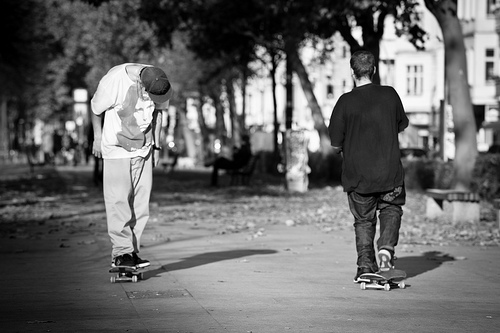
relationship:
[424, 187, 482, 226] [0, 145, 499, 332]
bench in park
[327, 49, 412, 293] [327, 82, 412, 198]
skateboarder wears shirt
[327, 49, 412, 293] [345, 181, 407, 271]
skateboarder wears jeans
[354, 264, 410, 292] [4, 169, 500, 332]
skateboard on pavement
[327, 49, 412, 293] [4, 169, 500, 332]
skateboarder on pavement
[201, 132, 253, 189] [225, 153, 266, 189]
man on bench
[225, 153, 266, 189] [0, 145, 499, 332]
bench in park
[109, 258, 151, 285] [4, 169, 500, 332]
skateboard on pavement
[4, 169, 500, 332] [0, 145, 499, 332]
pavement in park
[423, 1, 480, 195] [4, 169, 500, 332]
tree trunk next to pavement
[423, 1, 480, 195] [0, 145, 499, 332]
tree trunk in park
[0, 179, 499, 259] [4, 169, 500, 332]
leaves are over pavement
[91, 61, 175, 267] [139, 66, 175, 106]
man has head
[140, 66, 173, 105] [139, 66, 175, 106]
baseball hat on head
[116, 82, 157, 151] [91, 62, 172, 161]
jim morrison on tshirt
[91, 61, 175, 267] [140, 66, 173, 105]
man wearing baseball hat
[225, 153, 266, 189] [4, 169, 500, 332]
bench next to pavement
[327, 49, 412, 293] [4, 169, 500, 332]
skateboarder rolling along pavement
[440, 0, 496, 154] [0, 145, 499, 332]
building next to park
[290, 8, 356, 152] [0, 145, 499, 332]
building next to park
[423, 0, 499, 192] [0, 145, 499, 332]
tree next to park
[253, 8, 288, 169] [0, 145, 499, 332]
tree next to park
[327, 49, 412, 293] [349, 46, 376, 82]
skateboarder has hair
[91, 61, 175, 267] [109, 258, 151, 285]
man on skateboard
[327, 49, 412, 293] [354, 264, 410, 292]
skateboarder on skateboard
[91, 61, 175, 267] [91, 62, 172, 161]
man wears tshirt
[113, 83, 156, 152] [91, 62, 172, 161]
face on tshirt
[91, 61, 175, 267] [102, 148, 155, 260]
man wears pants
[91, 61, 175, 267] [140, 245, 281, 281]
man casts shadow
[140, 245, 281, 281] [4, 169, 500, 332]
shadow on pavement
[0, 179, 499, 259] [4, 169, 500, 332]
leaves are on pavement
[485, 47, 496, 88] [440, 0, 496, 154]
window in building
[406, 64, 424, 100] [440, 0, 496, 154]
window in building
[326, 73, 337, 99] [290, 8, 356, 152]
window in building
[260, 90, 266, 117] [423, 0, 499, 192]
window in tree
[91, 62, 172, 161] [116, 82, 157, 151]
tshirt shows jim morrison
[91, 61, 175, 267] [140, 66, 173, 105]
man wears baseball hat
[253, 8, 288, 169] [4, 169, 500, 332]
tree next to pavement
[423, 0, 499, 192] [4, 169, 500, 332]
tree next to pavement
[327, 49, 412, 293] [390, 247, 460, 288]
skateboarder casts shadow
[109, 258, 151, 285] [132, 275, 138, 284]
skateboard has wheel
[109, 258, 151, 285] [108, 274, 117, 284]
skateboard has wheel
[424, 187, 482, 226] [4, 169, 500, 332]
bench on pavement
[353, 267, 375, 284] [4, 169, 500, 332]
foot on pavement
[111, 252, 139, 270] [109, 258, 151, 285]
foot on skateboard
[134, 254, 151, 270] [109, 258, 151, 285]
foot on skateboard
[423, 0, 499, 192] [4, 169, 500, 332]
tree hangs over pavement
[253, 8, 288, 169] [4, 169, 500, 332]
tree hangs over pavement